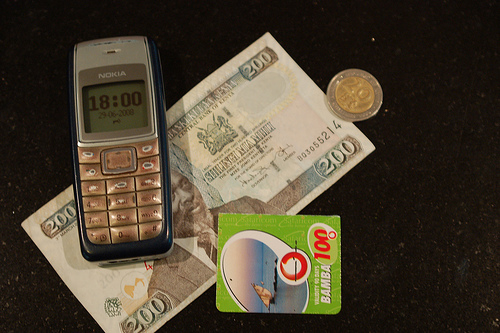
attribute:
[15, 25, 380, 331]
note — paper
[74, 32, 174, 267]
phone — large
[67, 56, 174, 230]
phone — old, nokia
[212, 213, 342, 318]
card — green 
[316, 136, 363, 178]
numbers — blak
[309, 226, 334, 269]
100 — red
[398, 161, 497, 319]
surface — black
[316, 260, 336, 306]
words — white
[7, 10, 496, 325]
table — black 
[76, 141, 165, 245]
buttons — multiple, copper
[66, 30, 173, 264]
cell phone — gray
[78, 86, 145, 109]
time — 18:00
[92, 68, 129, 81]
name — nokia